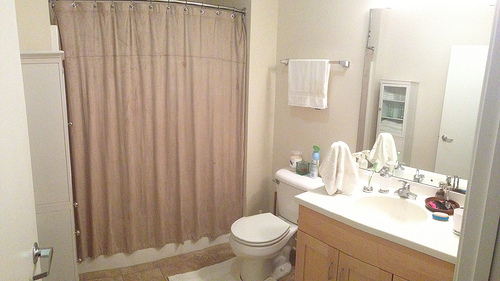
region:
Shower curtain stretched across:
[45, 6, 285, 253]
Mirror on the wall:
[362, 3, 494, 176]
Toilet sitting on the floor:
[217, 188, 297, 270]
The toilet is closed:
[230, 203, 280, 273]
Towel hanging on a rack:
[275, 53, 366, 143]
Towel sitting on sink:
[329, 139, 358, 198]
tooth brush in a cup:
[362, 157, 377, 209]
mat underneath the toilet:
[177, 251, 203, 277]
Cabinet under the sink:
[302, 213, 358, 273]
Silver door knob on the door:
[22, 224, 44, 279]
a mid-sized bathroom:
[14, 3, 489, 261]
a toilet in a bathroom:
[226, 167, 326, 278]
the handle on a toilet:
[268, 175, 284, 187]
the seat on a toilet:
[222, 208, 292, 251]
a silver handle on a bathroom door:
[25, 237, 61, 277]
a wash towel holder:
[278, 53, 353, 75]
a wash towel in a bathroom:
[278, 55, 357, 125]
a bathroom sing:
[367, 172, 431, 244]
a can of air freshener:
[308, 141, 322, 183]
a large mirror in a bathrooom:
[361, 0, 489, 180]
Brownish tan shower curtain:
[42, 4, 263, 256]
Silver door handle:
[23, 230, 65, 279]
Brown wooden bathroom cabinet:
[285, 202, 460, 280]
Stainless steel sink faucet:
[387, 177, 425, 205]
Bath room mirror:
[360, 7, 495, 196]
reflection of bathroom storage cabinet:
[373, 72, 425, 168]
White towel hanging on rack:
[281, 57, 337, 109]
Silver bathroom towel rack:
[274, 50, 354, 72]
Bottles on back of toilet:
[285, 138, 326, 183]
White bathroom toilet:
[224, 173, 339, 276]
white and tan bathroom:
[28, 7, 491, 273]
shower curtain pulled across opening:
[65, 0, 250, 250]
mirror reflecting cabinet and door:
[362, 6, 482, 178]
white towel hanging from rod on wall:
[277, 55, 347, 110]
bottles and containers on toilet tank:
[270, 141, 325, 186]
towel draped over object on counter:
[316, 130, 356, 200]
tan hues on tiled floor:
[101, 250, 216, 275]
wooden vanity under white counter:
[292, 205, 444, 272]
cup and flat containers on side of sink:
[422, 180, 458, 225]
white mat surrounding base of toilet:
[170, 245, 292, 277]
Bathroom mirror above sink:
[353, 5, 499, 196]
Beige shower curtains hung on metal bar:
[53, 0, 249, 261]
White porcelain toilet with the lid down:
[226, 163, 328, 279]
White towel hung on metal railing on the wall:
[276, 54, 353, 111]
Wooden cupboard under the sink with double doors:
[288, 203, 458, 279]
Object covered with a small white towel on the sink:
[315, 138, 363, 199]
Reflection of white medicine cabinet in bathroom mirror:
[371, 74, 423, 169]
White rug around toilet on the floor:
[160, 249, 299, 279]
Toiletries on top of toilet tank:
[288, 142, 323, 180]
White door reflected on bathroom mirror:
[432, 36, 492, 178]